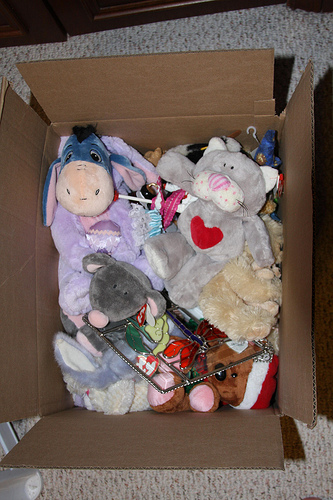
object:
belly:
[177, 197, 246, 260]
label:
[135, 354, 158, 377]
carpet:
[1, 5, 333, 500]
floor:
[0, 0, 333, 499]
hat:
[230, 353, 279, 410]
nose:
[95, 189, 100, 196]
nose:
[214, 362, 227, 381]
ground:
[0, 0, 333, 499]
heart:
[190, 216, 223, 251]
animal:
[42, 124, 284, 415]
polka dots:
[193, 170, 245, 214]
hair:
[72, 121, 95, 142]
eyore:
[34, 116, 170, 323]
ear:
[54, 330, 101, 372]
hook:
[247, 126, 262, 146]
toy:
[255, 131, 284, 169]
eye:
[224, 163, 227, 167]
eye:
[231, 166, 234, 170]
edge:
[0, 39, 318, 468]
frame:
[82, 296, 270, 394]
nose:
[88, 310, 109, 330]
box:
[0, 49, 317, 471]